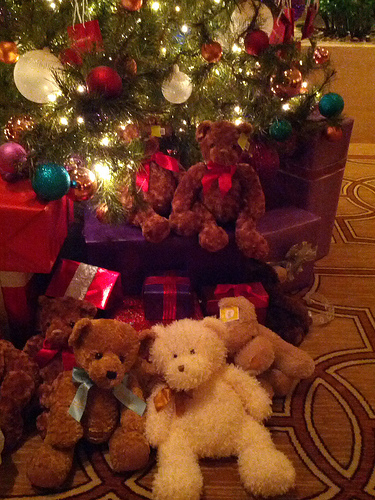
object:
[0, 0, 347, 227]
christmas tree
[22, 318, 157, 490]
teddy bear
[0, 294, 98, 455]
teddy bear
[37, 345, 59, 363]
ribbon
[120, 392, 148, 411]
ribbon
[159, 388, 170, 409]
ribbon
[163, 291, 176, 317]
ribbon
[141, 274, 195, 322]
present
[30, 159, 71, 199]
ornament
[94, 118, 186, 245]
bear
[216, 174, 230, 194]
ribbon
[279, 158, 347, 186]
ribbon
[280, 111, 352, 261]
present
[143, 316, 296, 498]
bear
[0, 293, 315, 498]
pile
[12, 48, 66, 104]
ornament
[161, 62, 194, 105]
ornament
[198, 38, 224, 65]
ornament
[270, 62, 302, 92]
ornament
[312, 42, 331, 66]
ornament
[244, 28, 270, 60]
ornament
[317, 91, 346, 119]
ornament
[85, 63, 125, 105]
ornament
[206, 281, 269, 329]
gift box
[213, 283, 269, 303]
bow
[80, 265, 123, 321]
box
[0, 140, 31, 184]
ornament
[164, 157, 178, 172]
ribbon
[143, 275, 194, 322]
box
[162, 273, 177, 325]
lace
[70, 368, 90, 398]
ribbon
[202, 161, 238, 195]
bow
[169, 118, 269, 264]
teddy bear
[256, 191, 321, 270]
chair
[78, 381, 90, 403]
ribbon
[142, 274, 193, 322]
wrapping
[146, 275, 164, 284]
ribbon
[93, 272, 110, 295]
paper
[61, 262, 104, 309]
trim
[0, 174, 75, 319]
table